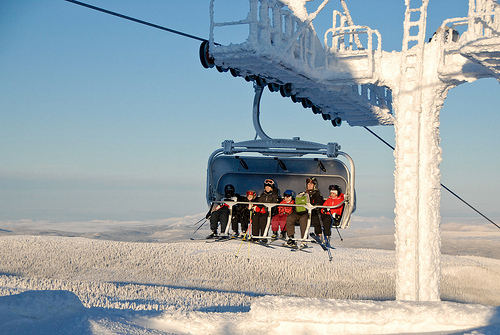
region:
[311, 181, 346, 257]
Child in ski lift wearing red jacket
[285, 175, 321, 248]
Person sitting in ski lift holding green backpack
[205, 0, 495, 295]
Ski lift tower covered in snow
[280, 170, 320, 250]
Person sitting in ski lift holding green backpack wearing brown pants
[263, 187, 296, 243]
Child in ski lift wearing red pants sitting next to person carrying green backpack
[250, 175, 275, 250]
Person sitting in ski lift wearing black jacket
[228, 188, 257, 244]
Child in ski lift wearing wearing black pants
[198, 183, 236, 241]
Child in ski lift wearing white shirt and black pants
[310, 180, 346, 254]
Child in ski lift wearing skiis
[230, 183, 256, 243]
Child in ski lift wearing skiis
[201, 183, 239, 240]
a person sitting in a ski lift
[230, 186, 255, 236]
a person sitting in a ski lift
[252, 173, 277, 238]
a person sitting in a ski lift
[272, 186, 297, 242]
a person sitting in a ski lift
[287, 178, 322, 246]
a person sitting in a ski lift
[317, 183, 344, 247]
a person sitting in a ski lift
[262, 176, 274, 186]
a pair of ski goggles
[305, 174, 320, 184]
a pair of ski goggles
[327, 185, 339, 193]
a pair of ski goggles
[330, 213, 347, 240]
a black ski pole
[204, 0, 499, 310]
Snow covering ski tower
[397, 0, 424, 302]
Ladder on skit tower is covered with snow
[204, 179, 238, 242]
Child wearing white shirt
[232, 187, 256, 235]
Child wearing black pants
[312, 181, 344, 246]
Child wearing black pants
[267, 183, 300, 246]
Child wearing red pants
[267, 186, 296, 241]
Child wearing red jacket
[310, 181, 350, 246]
Child wearing red jacket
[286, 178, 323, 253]
Person wearing brown pants and carrying green backpack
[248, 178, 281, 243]
Person wearing black pants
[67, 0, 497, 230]
Long black cable line next to frozen ski tower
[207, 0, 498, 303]
Ski tower covered in snow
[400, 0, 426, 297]
Ladder on ski tower covered in snow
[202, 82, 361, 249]
Ski lift passing next to ski tower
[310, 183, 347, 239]
Child sitting in ski lift wearing red jacket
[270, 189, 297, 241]
Child sitting next to person carrying green backpack is wearing red pants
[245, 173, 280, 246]
Person wearing black jacket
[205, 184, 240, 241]
Person sitting in ski lift wearing white shirt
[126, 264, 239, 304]
White snow on the ground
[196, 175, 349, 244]
Skiers riding in the ski lift.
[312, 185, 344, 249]
Skier with a red jacket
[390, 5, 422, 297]
Ski lift ladder covered in snow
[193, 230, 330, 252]
Skis worn by the skiers on the lift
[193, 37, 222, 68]
Guide wheel of the ski lift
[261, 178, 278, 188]
Skier wearing ski goggles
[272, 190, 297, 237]
Skier wearing a red jacket and red pants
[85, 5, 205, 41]
Ski lift guide wire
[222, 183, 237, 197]
Skier with a black helmet